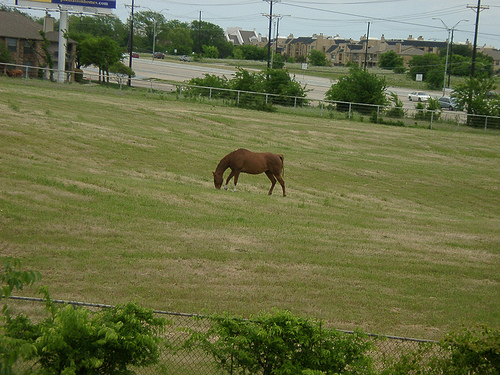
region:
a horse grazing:
[185, 127, 310, 207]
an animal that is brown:
[175, 115, 350, 250]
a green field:
[0, 60, 495, 355]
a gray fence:
[0, 260, 490, 370]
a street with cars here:
[90, 20, 490, 145]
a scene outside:
[5, 5, 490, 370]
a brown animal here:
[165, 131, 325, 211]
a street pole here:
[430, 1, 470, 107]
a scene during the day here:
[15, 10, 495, 350]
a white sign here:
[0, 1, 160, 82]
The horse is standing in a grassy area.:
[185, 127, 311, 213]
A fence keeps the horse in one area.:
[10, 285, 499, 367]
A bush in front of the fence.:
[20, 287, 177, 372]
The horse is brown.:
[187, 140, 315, 205]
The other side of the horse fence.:
[105, 70, 491, 130]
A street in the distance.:
[135, 41, 466, 106]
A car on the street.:
[391, 80, 432, 101]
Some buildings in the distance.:
[250, 33, 485, 68]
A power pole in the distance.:
[251, 2, 304, 83]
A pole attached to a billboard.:
[48, 0, 90, 92]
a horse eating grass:
[202, 131, 302, 196]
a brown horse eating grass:
[199, 144, 297, 203]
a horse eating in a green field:
[153, 131, 353, 263]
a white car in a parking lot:
[405, 86, 438, 106]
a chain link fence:
[6, 64, 489, 132]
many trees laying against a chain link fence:
[13, 297, 498, 372]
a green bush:
[187, 307, 372, 373]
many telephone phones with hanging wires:
[266, 0, 498, 56]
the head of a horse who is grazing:
[206, 170, 235, 192]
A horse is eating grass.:
[179, 130, 303, 215]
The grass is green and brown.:
[163, 225, 344, 290]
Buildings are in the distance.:
[217, 13, 494, 75]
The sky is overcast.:
[299, 4, 421, 23]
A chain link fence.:
[3, 291, 435, 373]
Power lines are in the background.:
[247, 0, 489, 48]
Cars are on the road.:
[361, 77, 475, 112]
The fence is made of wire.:
[0, 291, 462, 372]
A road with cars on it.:
[127, 49, 477, 121]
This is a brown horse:
[207, 144, 294, 202]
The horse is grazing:
[199, 155, 234, 195]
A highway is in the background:
[146, 55, 469, 112]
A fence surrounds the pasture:
[136, 75, 377, 118]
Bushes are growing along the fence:
[21, 295, 491, 370]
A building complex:
[274, 31, 474, 72]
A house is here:
[0, 8, 77, 82]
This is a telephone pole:
[466, 0, 492, 97]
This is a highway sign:
[298, 58, 311, 88]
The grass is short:
[96, 165, 206, 277]